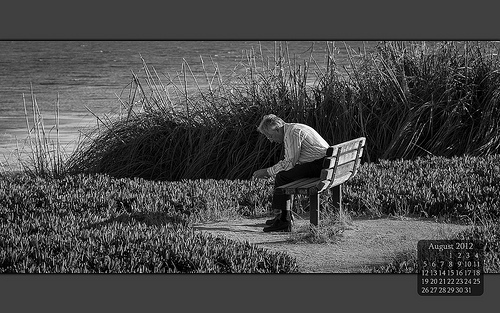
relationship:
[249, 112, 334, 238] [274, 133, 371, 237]
man on park bench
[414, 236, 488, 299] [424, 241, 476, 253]
calender for august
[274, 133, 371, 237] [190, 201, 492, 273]
park bench on platform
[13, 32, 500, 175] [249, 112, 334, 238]
grass to right of man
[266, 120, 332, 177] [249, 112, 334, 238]
shirt on man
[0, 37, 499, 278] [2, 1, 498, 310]
border on picture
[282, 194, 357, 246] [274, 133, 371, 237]
grass under park bench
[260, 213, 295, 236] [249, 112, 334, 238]
shoes are on man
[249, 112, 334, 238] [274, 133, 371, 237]
man sitting on park bench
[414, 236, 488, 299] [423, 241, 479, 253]
calender for august 2012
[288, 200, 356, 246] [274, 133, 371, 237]
weeds are growing around park bench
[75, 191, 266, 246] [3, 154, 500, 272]
shadow on grass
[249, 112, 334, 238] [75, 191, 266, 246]
man has shadow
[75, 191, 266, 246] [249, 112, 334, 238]
shadow of man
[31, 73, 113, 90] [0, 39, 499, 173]
ripples are in water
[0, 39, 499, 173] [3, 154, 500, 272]
water beyond grass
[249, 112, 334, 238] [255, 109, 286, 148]
man has head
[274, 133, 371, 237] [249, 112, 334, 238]
park bench below man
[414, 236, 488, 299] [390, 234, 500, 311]
calender in corner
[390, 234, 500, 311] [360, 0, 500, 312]
corner on right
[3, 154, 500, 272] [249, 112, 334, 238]
grass below man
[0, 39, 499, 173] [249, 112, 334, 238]
water next to man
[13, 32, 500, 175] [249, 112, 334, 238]
grass next to man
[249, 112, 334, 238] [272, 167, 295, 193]
man leaning on knees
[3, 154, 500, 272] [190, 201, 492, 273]
grass surrounds platform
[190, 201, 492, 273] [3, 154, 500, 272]
platform in grass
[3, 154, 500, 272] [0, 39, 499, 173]
grass beside water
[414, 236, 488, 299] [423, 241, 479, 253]
calender says august 2012